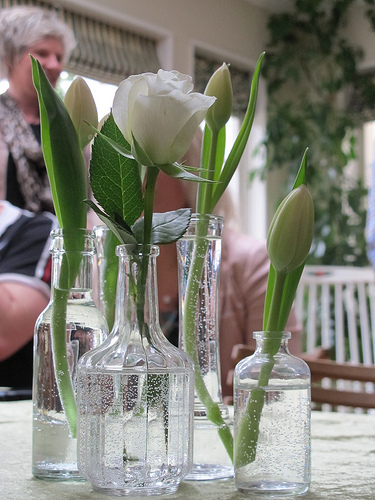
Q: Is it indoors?
A: Yes, it is indoors.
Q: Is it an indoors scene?
A: Yes, it is indoors.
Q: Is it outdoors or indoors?
A: It is indoors.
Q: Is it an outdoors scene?
A: No, it is indoors.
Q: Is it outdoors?
A: No, it is indoors.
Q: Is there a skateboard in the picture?
A: No, there are no skateboards.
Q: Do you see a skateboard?
A: No, there are no skateboards.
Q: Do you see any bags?
A: No, there are no bags.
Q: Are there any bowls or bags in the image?
A: No, there are no bags or bowls.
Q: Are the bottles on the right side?
A: Yes, the bottles are on the right of the image.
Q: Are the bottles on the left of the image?
A: No, the bottles are on the right of the image.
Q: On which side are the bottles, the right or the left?
A: The bottles are on the right of the image.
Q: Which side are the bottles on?
A: The bottles are on the right of the image.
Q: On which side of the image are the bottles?
A: The bottles are on the right of the image.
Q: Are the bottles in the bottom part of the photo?
A: Yes, the bottles are in the bottom of the image.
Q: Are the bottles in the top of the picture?
A: No, the bottles are in the bottom of the image.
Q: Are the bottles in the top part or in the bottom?
A: The bottles are in the bottom of the image.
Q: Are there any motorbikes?
A: No, there are no motorbikes.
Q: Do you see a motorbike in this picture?
A: No, there are no motorcycles.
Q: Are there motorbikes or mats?
A: No, there are no motorbikes or mats.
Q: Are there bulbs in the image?
A: No, there are no bulbs.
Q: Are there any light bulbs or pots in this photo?
A: No, there are no light bulbs or pots.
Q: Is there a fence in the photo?
A: No, there are no fences.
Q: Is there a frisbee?
A: No, there are no frisbees.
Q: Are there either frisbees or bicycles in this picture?
A: No, there are no frisbees or bicycles.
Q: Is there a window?
A: Yes, there is a window.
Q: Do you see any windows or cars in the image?
A: Yes, there is a window.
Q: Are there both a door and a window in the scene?
A: No, there is a window but no doors.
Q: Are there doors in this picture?
A: No, there are no doors.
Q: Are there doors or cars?
A: No, there are no doors or cars.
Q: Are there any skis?
A: No, there are no skis.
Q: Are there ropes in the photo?
A: No, there are no ropes.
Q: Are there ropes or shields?
A: No, there are no ropes or shields.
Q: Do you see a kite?
A: No, there are no kites.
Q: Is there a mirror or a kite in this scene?
A: No, there are no kites or mirrors.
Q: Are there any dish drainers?
A: No, there are no dish drainers.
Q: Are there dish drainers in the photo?
A: No, there are no dish drainers.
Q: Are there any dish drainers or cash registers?
A: No, there are no dish drainers or cash registers.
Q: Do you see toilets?
A: No, there are no toilets.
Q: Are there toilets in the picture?
A: No, there are no toilets.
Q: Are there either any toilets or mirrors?
A: No, there are no toilets or mirrors.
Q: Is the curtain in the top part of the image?
A: Yes, the curtain is in the top of the image.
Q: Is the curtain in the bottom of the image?
A: No, the curtain is in the top of the image.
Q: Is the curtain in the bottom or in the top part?
A: The curtain is in the top of the image.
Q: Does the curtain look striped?
A: Yes, the curtain is striped.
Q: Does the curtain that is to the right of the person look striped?
A: Yes, the curtain is striped.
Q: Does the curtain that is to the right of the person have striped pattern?
A: Yes, the curtain is striped.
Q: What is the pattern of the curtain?
A: The curtain is striped.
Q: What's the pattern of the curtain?
A: The curtain is striped.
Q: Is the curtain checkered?
A: No, the curtain is striped.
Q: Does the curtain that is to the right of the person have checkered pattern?
A: No, the curtain is striped.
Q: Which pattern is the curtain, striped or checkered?
A: The curtain is striped.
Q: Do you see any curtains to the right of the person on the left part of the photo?
A: Yes, there is a curtain to the right of the person.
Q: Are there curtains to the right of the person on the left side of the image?
A: Yes, there is a curtain to the right of the person.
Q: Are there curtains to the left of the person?
A: No, the curtain is to the right of the person.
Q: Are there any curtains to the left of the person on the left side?
A: No, the curtain is to the right of the person.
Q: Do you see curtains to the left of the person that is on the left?
A: No, the curtain is to the right of the person.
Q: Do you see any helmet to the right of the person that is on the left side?
A: No, there is a curtain to the right of the person.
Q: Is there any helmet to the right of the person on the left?
A: No, there is a curtain to the right of the person.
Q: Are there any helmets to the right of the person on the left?
A: No, there is a curtain to the right of the person.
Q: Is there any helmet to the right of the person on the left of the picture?
A: No, there is a curtain to the right of the person.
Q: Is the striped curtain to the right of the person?
A: Yes, the curtain is to the right of the person.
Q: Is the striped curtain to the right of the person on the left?
A: Yes, the curtain is to the right of the person.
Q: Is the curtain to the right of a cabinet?
A: No, the curtain is to the right of the person.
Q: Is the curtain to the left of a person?
A: No, the curtain is to the right of a person.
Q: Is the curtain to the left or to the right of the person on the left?
A: The curtain is to the right of the person.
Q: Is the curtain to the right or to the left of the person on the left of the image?
A: The curtain is to the right of the person.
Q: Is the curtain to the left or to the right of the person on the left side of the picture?
A: The curtain is to the right of the person.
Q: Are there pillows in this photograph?
A: No, there are no pillows.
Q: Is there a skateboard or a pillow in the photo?
A: No, there are no pillows or skateboards.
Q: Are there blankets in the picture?
A: No, there are no blankets.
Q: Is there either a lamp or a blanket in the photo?
A: No, there are no blankets or lamps.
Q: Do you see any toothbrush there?
A: No, there are no toothbrushes.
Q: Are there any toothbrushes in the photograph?
A: No, there are no toothbrushes.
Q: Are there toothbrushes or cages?
A: No, there are no toothbrushes or cages.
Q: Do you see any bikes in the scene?
A: No, there are no bikes.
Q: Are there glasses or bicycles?
A: No, there are no bicycles or glasses.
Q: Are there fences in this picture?
A: No, there are no fences.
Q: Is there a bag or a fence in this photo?
A: No, there are no fences or bags.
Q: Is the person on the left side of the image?
A: Yes, the person is on the left of the image.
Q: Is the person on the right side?
A: No, the person is on the left of the image.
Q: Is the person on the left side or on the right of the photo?
A: The person is on the left of the image.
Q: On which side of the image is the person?
A: The person is on the left of the image.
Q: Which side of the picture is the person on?
A: The person is on the left of the image.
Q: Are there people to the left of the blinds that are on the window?
A: Yes, there is a person to the left of the blinds.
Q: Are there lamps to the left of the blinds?
A: No, there is a person to the left of the blinds.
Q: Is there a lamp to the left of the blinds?
A: No, there is a person to the left of the blinds.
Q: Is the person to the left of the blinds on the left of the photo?
A: Yes, the person is to the left of the blinds.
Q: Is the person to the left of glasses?
A: No, the person is to the left of the blinds.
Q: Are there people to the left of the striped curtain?
A: Yes, there is a person to the left of the curtain.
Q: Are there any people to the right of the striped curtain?
A: No, the person is to the left of the curtain.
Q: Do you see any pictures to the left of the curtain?
A: No, there is a person to the left of the curtain.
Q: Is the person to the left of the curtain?
A: Yes, the person is to the left of the curtain.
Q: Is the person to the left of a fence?
A: No, the person is to the left of the curtain.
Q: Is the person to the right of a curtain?
A: No, the person is to the left of a curtain.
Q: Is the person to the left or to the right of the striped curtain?
A: The person is to the left of the curtain.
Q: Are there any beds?
A: No, there are no beds.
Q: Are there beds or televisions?
A: No, there are no beds or televisions.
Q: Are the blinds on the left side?
A: Yes, the blinds are on the left of the image.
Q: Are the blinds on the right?
A: No, the blinds are on the left of the image.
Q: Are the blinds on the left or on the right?
A: The blinds are on the left of the image.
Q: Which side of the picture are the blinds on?
A: The blinds are on the left of the image.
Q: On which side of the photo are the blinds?
A: The blinds are on the left of the image.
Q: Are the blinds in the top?
A: Yes, the blinds are in the top of the image.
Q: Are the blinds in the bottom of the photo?
A: No, the blinds are in the top of the image.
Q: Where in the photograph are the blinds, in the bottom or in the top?
A: The blinds are in the top of the image.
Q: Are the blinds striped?
A: Yes, the blinds are striped.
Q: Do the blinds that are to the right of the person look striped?
A: Yes, the blinds are striped.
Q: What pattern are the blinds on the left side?
A: The blinds are striped.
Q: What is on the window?
A: The blinds are on the window.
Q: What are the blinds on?
A: The blinds are on the window.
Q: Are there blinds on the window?
A: Yes, there are blinds on the window.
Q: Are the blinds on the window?
A: Yes, the blinds are on the window.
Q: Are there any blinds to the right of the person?
A: Yes, there are blinds to the right of the person.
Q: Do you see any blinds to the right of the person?
A: Yes, there are blinds to the right of the person.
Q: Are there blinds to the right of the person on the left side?
A: Yes, there are blinds to the right of the person.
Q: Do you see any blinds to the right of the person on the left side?
A: Yes, there are blinds to the right of the person.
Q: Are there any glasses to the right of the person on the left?
A: No, there are blinds to the right of the person.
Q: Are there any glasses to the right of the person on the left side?
A: No, there are blinds to the right of the person.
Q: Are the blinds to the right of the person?
A: Yes, the blinds are to the right of the person.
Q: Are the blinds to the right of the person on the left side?
A: Yes, the blinds are to the right of the person.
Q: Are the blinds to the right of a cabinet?
A: No, the blinds are to the right of the person.